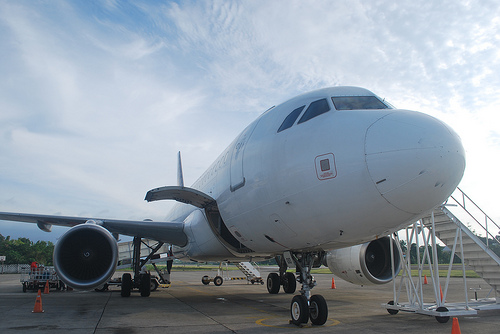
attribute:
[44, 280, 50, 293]
traffic cone — orange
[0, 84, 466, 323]
jumbo jet — parked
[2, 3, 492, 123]
sky — blue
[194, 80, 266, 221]
door — open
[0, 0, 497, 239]
sky — blue